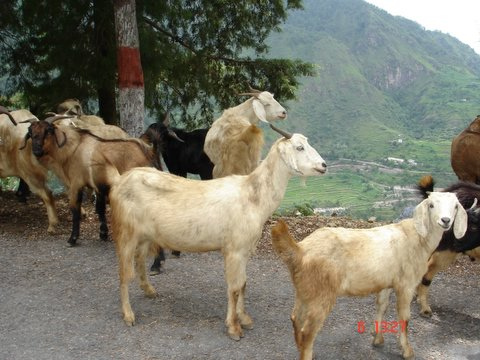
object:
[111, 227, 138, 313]
leg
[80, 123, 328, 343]
goat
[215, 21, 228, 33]
leaf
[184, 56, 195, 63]
leaf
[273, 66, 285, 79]
leaf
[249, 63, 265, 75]
leaf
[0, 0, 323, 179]
plant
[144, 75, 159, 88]
leaf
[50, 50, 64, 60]
leaf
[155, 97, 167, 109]
leaf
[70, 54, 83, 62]
leaf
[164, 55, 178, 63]
leaf